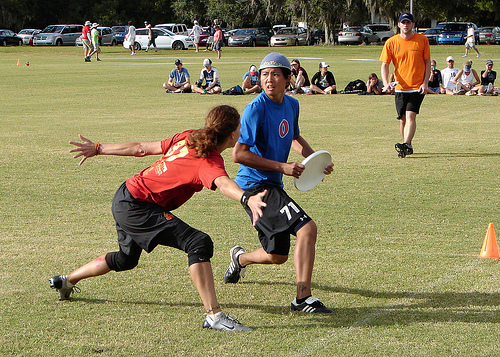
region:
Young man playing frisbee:
[226, 52, 335, 319]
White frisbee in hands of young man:
[291, 146, 336, 194]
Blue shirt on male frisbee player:
[236, 94, 305, 189]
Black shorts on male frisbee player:
[243, 177, 315, 256]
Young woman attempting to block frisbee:
[47, 101, 267, 336]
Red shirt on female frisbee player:
[125, 129, 226, 208]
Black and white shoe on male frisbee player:
[286, 292, 331, 317]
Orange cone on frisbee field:
[478, 219, 498, 264]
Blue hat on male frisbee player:
[254, 48, 294, 69]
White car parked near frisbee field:
[119, 24, 196, 50]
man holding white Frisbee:
[291, 146, 333, 196]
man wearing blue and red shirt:
[246, 101, 298, 173]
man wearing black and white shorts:
[263, 187, 305, 237]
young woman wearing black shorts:
[118, 196, 197, 256]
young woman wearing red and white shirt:
[156, 143, 198, 203]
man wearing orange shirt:
[381, 37, 426, 88]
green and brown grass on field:
[18, 71, 145, 133]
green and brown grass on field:
[350, 160, 459, 340]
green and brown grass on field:
[23, 301, 173, 346]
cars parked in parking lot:
[226, 21, 368, 50]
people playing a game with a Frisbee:
[70, 49, 445, 338]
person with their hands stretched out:
[62, 102, 272, 231]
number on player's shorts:
[253, 185, 310, 239]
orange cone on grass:
[477, 218, 498, 273]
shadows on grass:
[235, 271, 497, 337]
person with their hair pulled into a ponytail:
[180, 101, 242, 168]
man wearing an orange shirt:
[374, 10, 436, 97]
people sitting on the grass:
[156, 52, 498, 116]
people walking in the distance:
[66, 14, 236, 65]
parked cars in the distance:
[1, 8, 498, 55]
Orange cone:
[474, 218, 499, 267]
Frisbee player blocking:
[26, 97, 304, 342]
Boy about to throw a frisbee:
[198, 18, 347, 321]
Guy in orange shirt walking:
[380, 6, 441, 164]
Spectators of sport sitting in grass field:
[153, 56, 498, 110]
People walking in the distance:
[63, 20, 254, 65]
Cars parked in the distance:
[0, 20, 499, 52]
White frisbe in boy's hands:
[262, 121, 369, 233]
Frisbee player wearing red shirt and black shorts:
[40, 93, 280, 344]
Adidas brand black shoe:
[285, 288, 340, 321]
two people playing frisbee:
[140, 39, 341, 338]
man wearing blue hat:
[224, 40, 304, 102]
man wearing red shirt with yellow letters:
[65, 103, 235, 206]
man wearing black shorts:
[91, 144, 217, 285]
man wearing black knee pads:
[91, 238, 249, 285]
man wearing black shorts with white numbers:
[232, 163, 317, 268]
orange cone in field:
[409, 201, 499, 300]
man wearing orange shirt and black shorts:
[382, 29, 437, 114]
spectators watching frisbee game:
[129, 42, 497, 129]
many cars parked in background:
[11, 18, 388, 58]